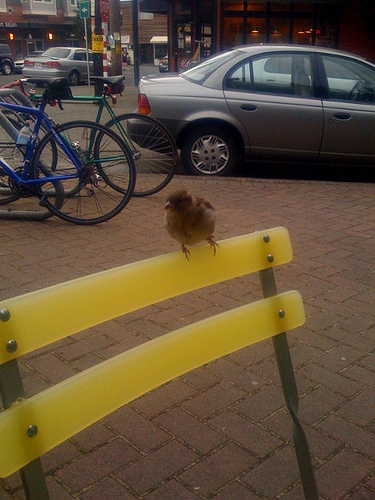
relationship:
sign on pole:
[89, 34, 104, 53] [92, 0, 103, 97]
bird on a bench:
[161, 188, 219, 261] [6, 219, 307, 497]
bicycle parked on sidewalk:
[0, 77, 135, 224] [1, 185, 373, 497]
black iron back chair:
[267, 339, 333, 481] [20, 265, 364, 467]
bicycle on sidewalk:
[6, 75, 177, 197] [1, 185, 373, 497]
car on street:
[20, 43, 110, 86] [5, 64, 127, 160]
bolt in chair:
[27, 423, 38, 436] [0, 226, 309, 478]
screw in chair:
[1, 310, 10, 320] [0, 226, 309, 478]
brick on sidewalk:
[178, 382, 241, 415] [1, 185, 373, 497]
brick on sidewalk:
[211, 409, 282, 454] [1, 185, 373, 497]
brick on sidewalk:
[119, 437, 194, 490] [1, 185, 373, 497]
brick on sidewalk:
[181, 439, 254, 493] [1, 185, 373, 497]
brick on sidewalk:
[157, 408, 224, 449] [1, 185, 373, 497]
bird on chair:
[161, 188, 219, 261] [0, 226, 309, 478]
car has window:
[124, 41, 373, 181] [224, 53, 312, 94]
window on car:
[223, 50, 319, 95] [124, 41, 373, 181]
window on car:
[324, 52, 374, 107] [124, 41, 373, 181]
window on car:
[186, 52, 236, 79] [124, 41, 373, 181]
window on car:
[43, 47, 70, 57] [22, 42, 103, 93]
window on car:
[73, 49, 89, 63] [22, 42, 103, 93]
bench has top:
[6, 219, 307, 497] [0, 225, 306, 479]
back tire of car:
[180, 122, 240, 177] [124, 41, 373, 181]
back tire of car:
[67, 69, 82, 88] [21, 44, 113, 84]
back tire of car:
[1, 61, 13, 75] [0, 40, 18, 74]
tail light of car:
[135, 85, 153, 118] [124, 41, 373, 181]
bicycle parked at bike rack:
[0, 77, 135, 224] [0, 87, 62, 221]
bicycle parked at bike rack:
[6, 75, 177, 197] [0, 87, 62, 221]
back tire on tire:
[180, 122, 240, 177] [180, 123, 240, 178]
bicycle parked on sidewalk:
[6, 75, 177, 197] [1, 185, 373, 497]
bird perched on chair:
[161, 188, 219, 261] [0, 226, 309, 478]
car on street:
[124, 41, 373, 181] [2, 65, 371, 181]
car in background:
[124, 41, 373, 181] [128, 7, 215, 44]